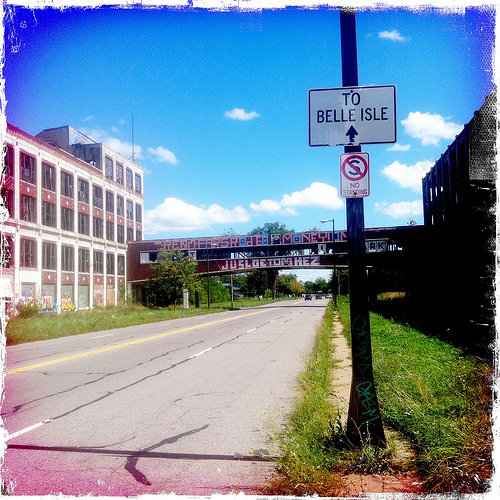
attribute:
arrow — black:
[342, 121, 360, 150]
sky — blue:
[12, 13, 481, 240]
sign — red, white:
[337, 159, 379, 220]